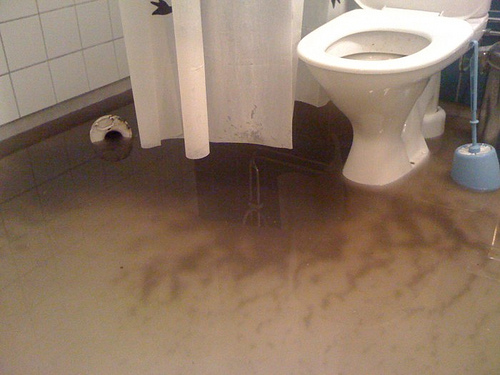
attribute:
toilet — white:
[299, 4, 470, 202]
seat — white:
[290, 4, 484, 79]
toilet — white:
[291, 1, 488, 193]